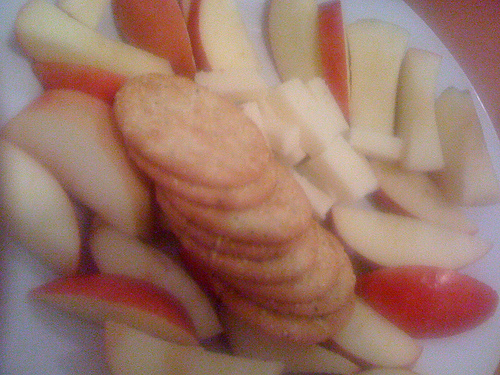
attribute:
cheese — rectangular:
[265, 76, 341, 157]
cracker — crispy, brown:
[126, 89, 242, 189]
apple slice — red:
[30, 270, 206, 346]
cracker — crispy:
[117, 80, 280, 187]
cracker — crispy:
[159, 163, 287, 213]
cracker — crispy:
[199, 209, 320, 241]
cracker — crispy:
[232, 237, 312, 283]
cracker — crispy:
[280, 244, 346, 301]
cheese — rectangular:
[350, 126, 402, 165]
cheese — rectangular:
[311, 137, 379, 200]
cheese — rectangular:
[309, 77, 351, 132]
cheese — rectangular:
[196, 68, 259, 98]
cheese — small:
[193, 66, 406, 219]